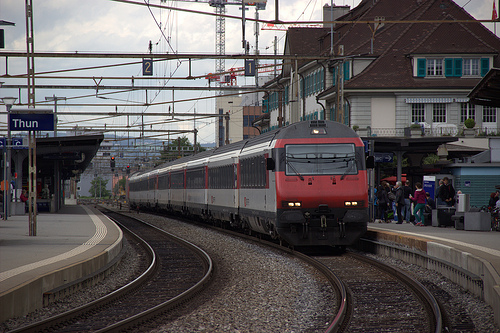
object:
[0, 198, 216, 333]
track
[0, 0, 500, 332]
picture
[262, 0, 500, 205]
building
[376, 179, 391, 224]
people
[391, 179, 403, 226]
people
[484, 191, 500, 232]
people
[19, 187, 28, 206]
people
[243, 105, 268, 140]
building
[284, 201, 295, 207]
light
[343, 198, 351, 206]
light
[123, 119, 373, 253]
train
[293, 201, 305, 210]
headlight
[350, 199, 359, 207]
headlight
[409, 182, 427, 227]
people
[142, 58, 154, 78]
sign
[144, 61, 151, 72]
2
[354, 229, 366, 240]
black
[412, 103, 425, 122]
window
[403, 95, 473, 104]
awning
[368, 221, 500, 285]
tarmac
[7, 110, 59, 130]
sign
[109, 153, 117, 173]
traffic light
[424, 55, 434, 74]
window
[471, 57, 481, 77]
window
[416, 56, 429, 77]
shutters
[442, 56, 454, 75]
shutters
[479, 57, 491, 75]
shutters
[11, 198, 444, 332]
train track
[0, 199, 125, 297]
tarmac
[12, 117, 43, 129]
word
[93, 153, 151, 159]
post